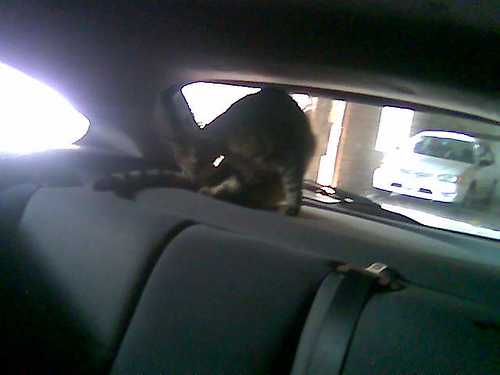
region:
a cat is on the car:
[96, 86, 313, 211]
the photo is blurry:
[0, 0, 497, 371]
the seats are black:
[6, 187, 496, 373]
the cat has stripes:
[95, 80, 316, 219]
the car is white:
[373, 131, 494, 199]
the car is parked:
[372, 135, 494, 200]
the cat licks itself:
[92, 85, 316, 216]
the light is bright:
[0, 64, 95, 152]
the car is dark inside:
[1, 0, 498, 374]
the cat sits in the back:
[93, 83, 315, 213]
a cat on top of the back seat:
[143, 101, 381, 247]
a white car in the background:
[375, 123, 477, 235]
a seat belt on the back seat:
[343, 243, 435, 350]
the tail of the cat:
[125, 158, 195, 202]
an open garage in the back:
[345, 115, 499, 204]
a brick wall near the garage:
[321, 98, 408, 189]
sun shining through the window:
[0, 103, 82, 175]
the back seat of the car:
[42, 182, 232, 370]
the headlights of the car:
[384, 163, 476, 187]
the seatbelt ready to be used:
[293, 249, 433, 370]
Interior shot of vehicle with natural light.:
[5, 8, 496, 368]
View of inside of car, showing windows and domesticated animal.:
[5, 7, 495, 357]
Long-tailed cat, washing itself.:
[122, 93, 319, 214]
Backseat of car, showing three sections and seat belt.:
[5, 165, 497, 374]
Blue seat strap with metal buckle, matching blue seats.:
[312, 258, 422, 373]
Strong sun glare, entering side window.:
[0, 65, 97, 170]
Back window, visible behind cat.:
[195, 70, 497, 233]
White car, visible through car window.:
[375, 126, 482, 206]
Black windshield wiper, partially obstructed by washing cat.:
[305, 170, 415, 230]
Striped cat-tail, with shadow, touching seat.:
[95, 160, 189, 202]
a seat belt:
[348, 246, 425, 304]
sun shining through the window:
[14, 86, 101, 162]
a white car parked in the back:
[390, 128, 497, 203]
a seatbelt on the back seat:
[346, 248, 401, 281]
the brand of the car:
[406, 168, 421, 183]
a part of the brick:
[333, 117, 374, 179]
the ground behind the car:
[396, 206, 486, 236]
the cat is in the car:
[146, 91, 330, 235]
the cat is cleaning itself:
[94, 62, 326, 257]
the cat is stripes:
[111, 67, 385, 265]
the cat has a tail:
[51, 78, 338, 265]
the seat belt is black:
[300, 235, 376, 372]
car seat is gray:
[21, 158, 344, 371]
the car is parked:
[338, 114, 481, 257]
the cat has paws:
[182, 152, 341, 257]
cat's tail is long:
[89, 145, 227, 209]